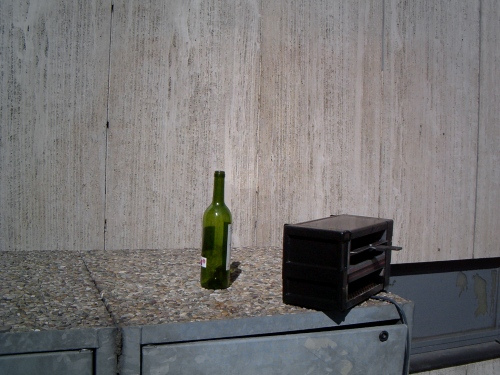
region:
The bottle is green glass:
[191, 163, 263, 322]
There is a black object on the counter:
[278, 207, 420, 339]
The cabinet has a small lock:
[133, 326, 423, 373]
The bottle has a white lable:
[195, 168, 246, 297]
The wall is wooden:
[3, 5, 498, 267]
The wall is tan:
[3, 4, 498, 248]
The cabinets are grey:
[8, 312, 430, 373]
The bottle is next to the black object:
[171, 168, 435, 333]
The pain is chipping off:
[439, 269, 499, 345]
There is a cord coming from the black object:
[279, 207, 434, 371]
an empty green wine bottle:
[197, 160, 245, 299]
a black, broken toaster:
[289, 192, 405, 312]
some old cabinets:
[121, 317, 404, 372]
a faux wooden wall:
[19, 20, 153, 247]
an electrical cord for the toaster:
[376, 295, 444, 372]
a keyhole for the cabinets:
[371, 330, 391, 343]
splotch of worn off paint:
[448, 276, 498, 299]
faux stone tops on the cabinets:
[36, 250, 183, 325]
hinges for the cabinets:
[111, 322, 135, 361]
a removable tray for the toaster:
[345, 237, 409, 268]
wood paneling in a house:
[1, 14, 495, 257]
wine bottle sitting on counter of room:
[198, 171, 237, 288]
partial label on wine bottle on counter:
[224, 222, 234, 274]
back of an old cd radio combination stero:
[278, 210, 404, 317]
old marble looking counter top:
[1, 251, 219, 320]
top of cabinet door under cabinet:
[125, 314, 411, 367]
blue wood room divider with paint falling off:
[388, 266, 498, 365]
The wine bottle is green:
[198, 168, 238, 288]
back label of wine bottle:
[193, 254, 210, 269]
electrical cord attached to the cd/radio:
[374, 294, 411, 371]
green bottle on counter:
[162, 134, 266, 305]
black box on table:
[271, 181, 427, 321]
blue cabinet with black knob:
[330, 320, 395, 373]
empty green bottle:
[163, 164, 255, 295]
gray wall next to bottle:
[165, 17, 291, 97]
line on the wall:
[55, 125, 142, 201]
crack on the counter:
[45, 242, 121, 322]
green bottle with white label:
[176, 175, 266, 285]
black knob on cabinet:
[366, 316, 397, 351]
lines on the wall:
[66, 13, 494, 128]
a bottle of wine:
[191, 159, 248, 310]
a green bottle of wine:
[194, 158, 246, 295]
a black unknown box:
[278, 187, 421, 318]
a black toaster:
[276, 187, 418, 334]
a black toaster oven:
[282, 192, 420, 321]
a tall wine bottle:
[184, 159, 250, 313]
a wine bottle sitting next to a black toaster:
[186, 138, 445, 323]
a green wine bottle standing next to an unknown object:
[197, 166, 430, 323]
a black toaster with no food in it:
[273, 191, 418, 331]